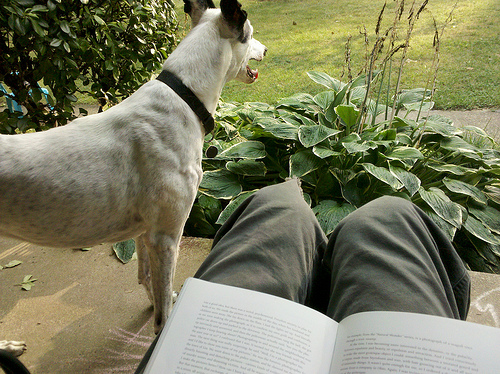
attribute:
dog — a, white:
[0, 0, 273, 325]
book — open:
[133, 270, 497, 371]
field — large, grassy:
[271, 2, 371, 82]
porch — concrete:
[0, 240, 134, 371]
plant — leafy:
[288, 88, 488, 231]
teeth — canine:
[248, 65, 261, 73]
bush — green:
[196, 60, 497, 265]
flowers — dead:
[355, 122, 493, 211]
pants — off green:
[201, 186, 477, 319]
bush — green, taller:
[2, 4, 168, 129]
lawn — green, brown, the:
[0, 3, 499, 116]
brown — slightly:
[450, 24, 470, 35]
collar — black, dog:
[154, 65, 216, 135]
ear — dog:
[217, 0, 254, 39]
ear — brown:
[217, 0, 250, 41]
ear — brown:
[174, 1, 216, 29]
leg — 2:
[126, 228, 157, 304]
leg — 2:
[142, 187, 192, 332]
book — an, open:
[121, 267, 499, 367]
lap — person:
[202, 164, 472, 325]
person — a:
[194, 165, 480, 320]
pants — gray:
[194, 161, 479, 322]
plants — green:
[208, 55, 498, 271]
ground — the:
[150, 69, 499, 241]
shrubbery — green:
[0, 0, 181, 149]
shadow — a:
[277, 29, 337, 74]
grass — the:
[180, 10, 498, 117]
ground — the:
[1, 234, 229, 367]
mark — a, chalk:
[472, 287, 498, 323]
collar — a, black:
[149, 62, 231, 149]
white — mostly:
[90, 128, 110, 145]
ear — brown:
[212, 1, 251, 43]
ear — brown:
[174, 1, 221, 24]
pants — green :
[202, 148, 472, 322]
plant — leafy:
[189, 29, 499, 268]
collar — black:
[142, 52, 234, 140]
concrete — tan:
[3, 200, 208, 370]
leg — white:
[138, 176, 182, 338]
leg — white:
[129, 228, 159, 304]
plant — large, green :
[172, 50, 498, 313]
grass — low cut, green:
[2, 0, 499, 120]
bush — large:
[0, 2, 180, 135]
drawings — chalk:
[91, 322, 158, 372]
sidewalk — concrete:
[372, 104, 499, 149]